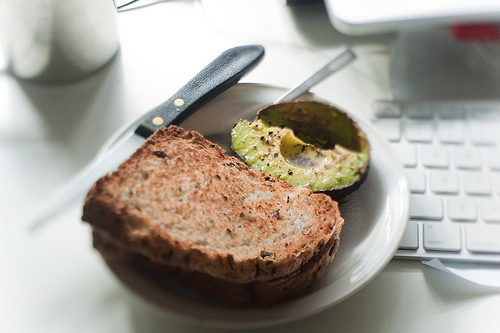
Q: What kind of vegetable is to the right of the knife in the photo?
A: The vegetable is an avocado.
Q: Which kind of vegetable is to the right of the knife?
A: The vegetable is an avocado.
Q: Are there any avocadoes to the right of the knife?
A: Yes, there is an avocado to the right of the knife.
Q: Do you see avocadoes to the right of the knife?
A: Yes, there is an avocado to the right of the knife.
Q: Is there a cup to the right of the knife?
A: No, there is an avocado to the right of the knife.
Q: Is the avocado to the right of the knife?
A: Yes, the avocado is to the right of the knife.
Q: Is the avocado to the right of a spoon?
A: No, the avocado is to the right of the knife.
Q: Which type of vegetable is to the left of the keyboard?
A: The vegetable is an avocado.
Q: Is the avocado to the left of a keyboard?
A: Yes, the avocado is to the left of a keyboard.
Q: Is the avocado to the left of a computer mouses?
A: No, the avocado is to the left of a keyboard.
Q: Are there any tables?
A: Yes, there is a table.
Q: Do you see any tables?
A: Yes, there is a table.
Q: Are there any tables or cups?
A: Yes, there is a table.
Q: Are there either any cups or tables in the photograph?
A: Yes, there is a table.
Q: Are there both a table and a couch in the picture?
A: No, there is a table but no couches.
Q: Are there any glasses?
A: No, there are no glasses.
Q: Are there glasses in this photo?
A: No, there are no glasses.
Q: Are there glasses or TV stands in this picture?
A: No, there are no glasses or TV stands.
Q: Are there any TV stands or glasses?
A: No, there are no glasses or TV stands.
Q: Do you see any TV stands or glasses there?
A: No, there are no glasses or TV stands.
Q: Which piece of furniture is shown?
A: The piece of furniture is a table.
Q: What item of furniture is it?
A: The piece of furniture is a table.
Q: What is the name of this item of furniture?
A: This is a table.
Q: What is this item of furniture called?
A: This is a table.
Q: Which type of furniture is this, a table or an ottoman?
A: This is a table.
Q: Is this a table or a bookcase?
A: This is a table.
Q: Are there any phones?
A: No, there are no phones.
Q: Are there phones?
A: No, there are no phones.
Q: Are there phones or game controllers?
A: No, there are no phones or game controllers.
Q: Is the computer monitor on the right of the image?
A: Yes, the computer monitor is on the right of the image.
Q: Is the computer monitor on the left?
A: No, the computer monitor is on the right of the image.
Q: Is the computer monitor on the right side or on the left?
A: The computer monitor is on the right of the image.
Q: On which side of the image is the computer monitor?
A: The computer monitor is on the right of the image.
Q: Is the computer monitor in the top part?
A: Yes, the computer monitor is in the top of the image.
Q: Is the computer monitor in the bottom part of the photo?
A: No, the computer monitor is in the top of the image.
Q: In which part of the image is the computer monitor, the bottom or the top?
A: The computer monitor is in the top of the image.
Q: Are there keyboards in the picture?
A: Yes, there is a keyboard.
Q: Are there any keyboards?
A: Yes, there is a keyboard.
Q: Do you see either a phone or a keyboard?
A: Yes, there is a keyboard.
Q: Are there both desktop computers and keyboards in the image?
A: No, there is a keyboard but no desktop computers.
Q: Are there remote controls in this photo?
A: No, there are no remote controls.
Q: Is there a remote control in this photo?
A: No, there are no remote controls.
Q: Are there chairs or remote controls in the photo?
A: No, there are no remote controls or chairs.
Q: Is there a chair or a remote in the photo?
A: No, there are no remote controls or chairs.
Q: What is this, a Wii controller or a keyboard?
A: This is a keyboard.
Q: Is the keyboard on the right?
A: Yes, the keyboard is on the right of the image.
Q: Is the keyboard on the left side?
A: No, the keyboard is on the right of the image.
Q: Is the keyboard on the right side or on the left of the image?
A: The keyboard is on the right of the image.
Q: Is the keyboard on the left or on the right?
A: The keyboard is on the right of the image.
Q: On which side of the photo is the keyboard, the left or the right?
A: The keyboard is on the right of the image.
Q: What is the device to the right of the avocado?
A: The device is a keyboard.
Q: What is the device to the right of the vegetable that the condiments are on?
A: The device is a keyboard.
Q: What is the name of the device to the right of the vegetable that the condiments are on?
A: The device is a keyboard.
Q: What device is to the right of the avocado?
A: The device is a keyboard.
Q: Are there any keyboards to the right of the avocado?
A: Yes, there is a keyboard to the right of the avocado.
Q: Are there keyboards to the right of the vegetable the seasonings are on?
A: Yes, there is a keyboard to the right of the avocado.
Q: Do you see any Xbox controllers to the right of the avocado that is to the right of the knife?
A: No, there is a keyboard to the right of the avocado.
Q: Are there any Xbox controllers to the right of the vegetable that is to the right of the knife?
A: No, there is a keyboard to the right of the avocado.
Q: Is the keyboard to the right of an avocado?
A: Yes, the keyboard is to the right of an avocado.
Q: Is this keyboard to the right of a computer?
A: No, the keyboard is to the right of an avocado.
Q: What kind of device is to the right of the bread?
A: The device is a keyboard.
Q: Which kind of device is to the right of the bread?
A: The device is a keyboard.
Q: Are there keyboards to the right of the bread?
A: Yes, there is a keyboard to the right of the bread.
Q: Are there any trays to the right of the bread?
A: No, there is a keyboard to the right of the bread.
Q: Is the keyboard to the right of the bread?
A: Yes, the keyboard is to the right of the bread.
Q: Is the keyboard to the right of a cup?
A: No, the keyboard is to the right of the bread.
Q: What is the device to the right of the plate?
A: The device is a keyboard.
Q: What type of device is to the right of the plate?
A: The device is a keyboard.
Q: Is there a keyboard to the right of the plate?
A: Yes, there is a keyboard to the right of the plate.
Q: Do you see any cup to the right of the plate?
A: No, there is a keyboard to the right of the plate.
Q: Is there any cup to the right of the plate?
A: No, there is a keyboard to the right of the plate.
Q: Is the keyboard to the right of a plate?
A: Yes, the keyboard is to the right of a plate.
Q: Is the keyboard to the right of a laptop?
A: No, the keyboard is to the right of a plate.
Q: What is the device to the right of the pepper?
A: The device is a keyboard.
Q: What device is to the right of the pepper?
A: The device is a keyboard.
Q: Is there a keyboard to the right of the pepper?
A: Yes, there is a keyboard to the right of the pepper.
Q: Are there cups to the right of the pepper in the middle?
A: No, there is a keyboard to the right of the pepper.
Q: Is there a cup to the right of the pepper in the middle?
A: No, there is a keyboard to the right of the pepper.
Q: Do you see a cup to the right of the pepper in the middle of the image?
A: No, there is a keyboard to the right of the pepper.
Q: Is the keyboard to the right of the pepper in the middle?
A: Yes, the keyboard is to the right of the pepper.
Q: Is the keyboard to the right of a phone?
A: No, the keyboard is to the right of the pepper.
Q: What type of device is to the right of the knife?
A: The device is a keyboard.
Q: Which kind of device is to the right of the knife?
A: The device is a keyboard.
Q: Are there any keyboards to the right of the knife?
A: Yes, there is a keyboard to the right of the knife.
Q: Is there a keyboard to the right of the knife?
A: Yes, there is a keyboard to the right of the knife.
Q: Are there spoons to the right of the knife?
A: No, there is a keyboard to the right of the knife.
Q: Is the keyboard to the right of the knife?
A: Yes, the keyboard is to the right of the knife.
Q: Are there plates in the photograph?
A: Yes, there is a plate.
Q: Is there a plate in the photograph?
A: Yes, there is a plate.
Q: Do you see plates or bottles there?
A: Yes, there is a plate.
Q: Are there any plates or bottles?
A: Yes, there is a plate.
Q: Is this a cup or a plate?
A: This is a plate.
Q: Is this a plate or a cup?
A: This is a plate.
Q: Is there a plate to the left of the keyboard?
A: Yes, there is a plate to the left of the keyboard.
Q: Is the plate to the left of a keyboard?
A: Yes, the plate is to the left of a keyboard.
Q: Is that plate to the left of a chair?
A: No, the plate is to the left of a keyboard.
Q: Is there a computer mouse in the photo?
A: Yes, there is a computer mouse.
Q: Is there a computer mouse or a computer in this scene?
A: Yes, there is a computer mouse.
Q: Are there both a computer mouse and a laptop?
A: No, there is a computer mouse but no laptops.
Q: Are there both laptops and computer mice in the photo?
A: No, there is a computer mouse but no laptops.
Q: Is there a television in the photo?
A: No, there are no televisions.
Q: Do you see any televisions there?
A: No, there are no televisions.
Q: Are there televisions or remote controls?
A: No, there are no televisions or remote controls.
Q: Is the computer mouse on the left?
A: Yes, the computer mouse is on the left of the image.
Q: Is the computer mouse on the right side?
A: No, the computer mouse is on the left of the image.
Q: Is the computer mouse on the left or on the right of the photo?
A: The computer mouse is on the left of the image.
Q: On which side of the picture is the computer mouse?
A: The computer mouse is on the left of the image.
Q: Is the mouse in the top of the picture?
A: Yes, the mouse is in the top of the image.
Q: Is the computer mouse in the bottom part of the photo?
A: No, the computer mouse is in the top of the image.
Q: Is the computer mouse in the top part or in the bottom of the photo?
A: The computer mouse is in the top of the image.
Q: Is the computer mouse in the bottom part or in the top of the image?
A: The computer mouse is in the top of the image.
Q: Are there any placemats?
A: No, there are no placemats.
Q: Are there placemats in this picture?
A: No, there are no placemats.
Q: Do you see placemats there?
A: No, there are no placemats.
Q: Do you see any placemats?
A: No, there are no placemats.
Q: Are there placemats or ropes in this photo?
A: No, there are no placemats or ropes.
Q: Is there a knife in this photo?
A: Yes, there is a knife.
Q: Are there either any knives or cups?
A: Yes, there is a knife.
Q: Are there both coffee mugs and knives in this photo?
A: No, there is a knife but no coffee mugs.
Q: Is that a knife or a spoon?
A: That is a knife.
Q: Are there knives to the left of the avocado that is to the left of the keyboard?
A: Yes, there is a knife to the left of the avocado.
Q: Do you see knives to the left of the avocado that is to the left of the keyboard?
A: Yes, there is a knife to the left of the avocado.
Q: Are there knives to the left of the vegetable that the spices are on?
A: Yes, there is a knife to the left of the avocado.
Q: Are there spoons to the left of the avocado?
A: No, there is a knife to the left of the avocado.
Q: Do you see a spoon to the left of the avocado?
A: No, there is a knife to the left of the avocado.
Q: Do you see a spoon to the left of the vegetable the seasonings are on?
A: No, there is a knife to the left of the avocado.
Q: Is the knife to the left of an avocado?
A: Yes, the knife is to the left of an avocado.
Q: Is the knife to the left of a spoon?
A: No, the knife is to the left of an avocado.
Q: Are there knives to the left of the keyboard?
A: Yes, there is a knife to the left of the keyboard.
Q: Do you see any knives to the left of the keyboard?
A: Yes, there is a knife to the left of the keyboard.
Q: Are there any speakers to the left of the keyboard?
A: No, there is a knife to the left of the keyboard.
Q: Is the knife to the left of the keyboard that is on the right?
A: Yes, the knife is to the left of the keyboard.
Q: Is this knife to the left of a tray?
A: No, the knife is to the left of the keyboard.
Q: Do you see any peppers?
A: Yes, there is a pepper.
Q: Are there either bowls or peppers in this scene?
A: Yes, there is a pepper.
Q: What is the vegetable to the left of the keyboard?
A: The vegetable is a pepper.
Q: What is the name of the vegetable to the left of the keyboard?
A: The vegetable is a pepper.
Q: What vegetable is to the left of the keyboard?
A: The vegetable is a pepper.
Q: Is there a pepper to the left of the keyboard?
A: Yes, there is a pepper to the left of the keyboard.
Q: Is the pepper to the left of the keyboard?
A: Yes, the pepper is to the left of the keyboard.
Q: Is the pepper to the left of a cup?
A: No, the pepper is to the left of the keyboard.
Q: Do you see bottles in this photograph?
A: No, there are no bottles.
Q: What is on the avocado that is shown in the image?
A: The spices are on the avocado.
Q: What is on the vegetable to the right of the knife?
A: The spices are on the avocado.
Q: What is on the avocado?
A: The spices are on the avocado.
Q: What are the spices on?
A: The spices are on the avocado.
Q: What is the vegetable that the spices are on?
A: The vegetable is an avocado.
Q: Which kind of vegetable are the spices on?
A: The spices are on the avocado.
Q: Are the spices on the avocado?
A: Yes, the spices are on the avocado.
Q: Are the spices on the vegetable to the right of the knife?
A: Yes, the spices are on the avocado.